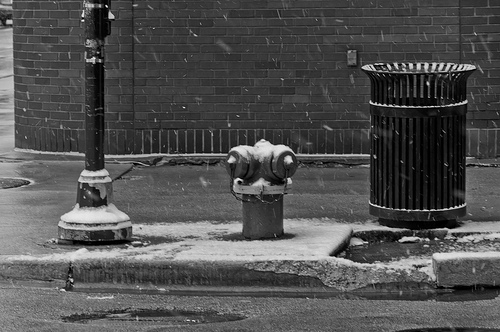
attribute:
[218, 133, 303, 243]
hyrdrant — fire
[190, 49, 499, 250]
can — trash can 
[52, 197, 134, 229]
snow — on the bottom 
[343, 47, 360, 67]
box — small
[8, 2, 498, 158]
wall — brick, brick wall 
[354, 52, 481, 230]
trash can — metallic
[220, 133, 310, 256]
fire hydrant — small 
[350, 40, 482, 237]
bin — metal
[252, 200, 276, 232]
hydrant — fire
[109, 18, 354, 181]
snow bits — in the air 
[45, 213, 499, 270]
snow — small patch of snow 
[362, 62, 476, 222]
trash can — metal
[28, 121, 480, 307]
sidewalk — wet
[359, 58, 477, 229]
bin — dust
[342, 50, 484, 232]
trash can — metal 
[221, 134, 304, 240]
hydrant — fire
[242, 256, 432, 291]
curb — damaged